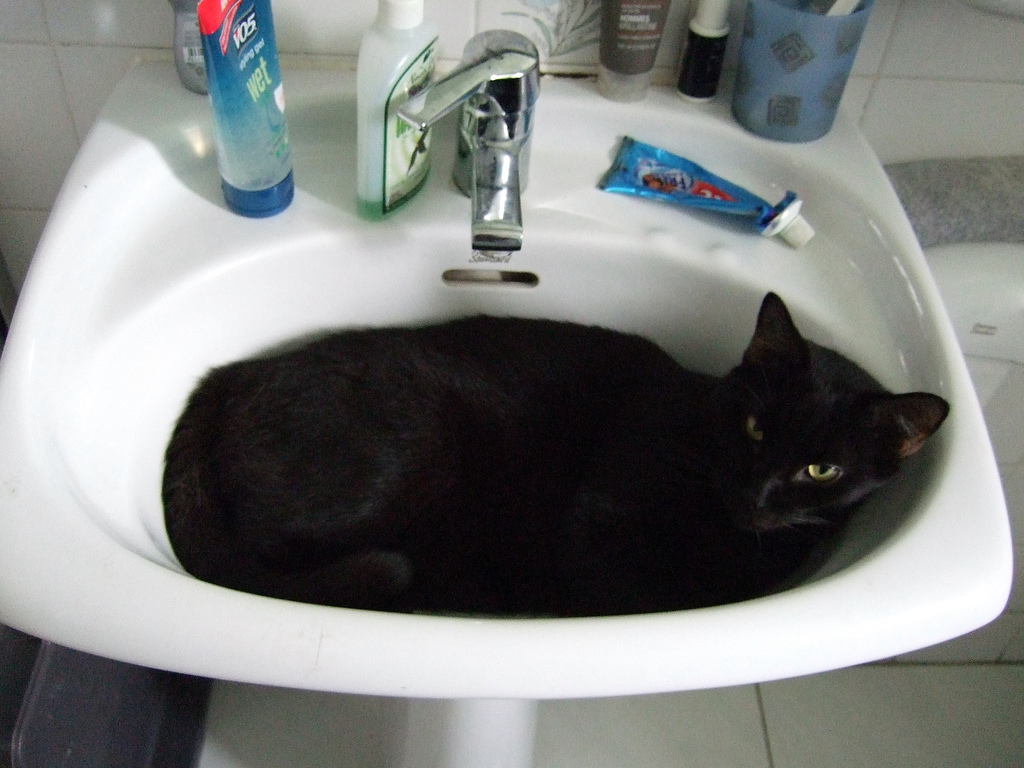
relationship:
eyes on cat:
[732, 412, 847, 488] [162, 292, 954, 618]